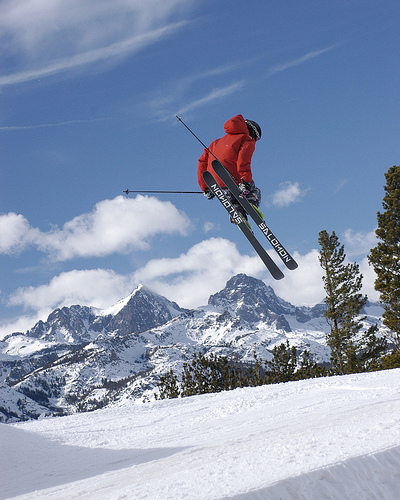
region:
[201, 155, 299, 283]
skis on person's feet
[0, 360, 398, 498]
ski hill covered in snow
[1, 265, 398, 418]
Snow-covered mountain behind ski hill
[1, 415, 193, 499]
shadow on ski hill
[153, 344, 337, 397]
bushes along ski hill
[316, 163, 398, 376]
coniferous trees at top of hill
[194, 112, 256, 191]
red, hooded winter coat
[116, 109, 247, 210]
ski poles in man's hands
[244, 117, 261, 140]
goggles on man's head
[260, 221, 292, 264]
"Salomon" label on right ski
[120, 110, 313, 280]
SKIER DOING HIGH JUMP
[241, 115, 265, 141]
HEAD OF JUMPING SKIER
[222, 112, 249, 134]
JACKET HOOD OF JUMPING SKIER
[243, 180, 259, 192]
GLOVED HAND OF JUMPING SKIER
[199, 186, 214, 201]
GLOVED HAND OF JUMPING SKIE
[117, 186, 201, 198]
SKI POLE OF ATHLETIC PERSON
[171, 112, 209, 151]
PART OF ATHLETIC SKIERS POLE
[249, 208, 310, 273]
PART OF ATHLETIC PERSON'S SKI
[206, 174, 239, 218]
PART OF ATHLETIC PERSON'S SKI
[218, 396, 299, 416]
SKI TRACKS IN SNOW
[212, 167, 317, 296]
The person is wearing skis.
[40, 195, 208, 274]
The clouds in sky.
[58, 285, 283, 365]
Mountains covered in snow.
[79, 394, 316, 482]
Snow on the ground.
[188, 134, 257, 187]
the person is wearing an orange jacket.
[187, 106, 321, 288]
The man is skiing in the air.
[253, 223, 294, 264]
Writing on the ski.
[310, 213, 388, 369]
The trees are tall.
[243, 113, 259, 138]
The person is wearing black helmet.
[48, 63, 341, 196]
The sky is clear and blue.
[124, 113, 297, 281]
The skier is airborne.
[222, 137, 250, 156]
The jacket is red.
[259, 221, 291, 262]
The word Salomon is on the ski.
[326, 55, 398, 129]
The sky is blue.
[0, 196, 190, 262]
Clouds are in the sky.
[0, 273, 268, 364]
Mountains are in the background.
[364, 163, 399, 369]
Trees are on the mountain.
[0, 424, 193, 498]
A shadow is on the mountain.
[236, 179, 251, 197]
The skier wears gloves.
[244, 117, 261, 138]
The skier wears a hat.